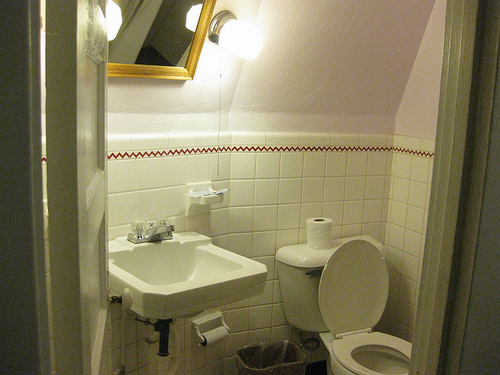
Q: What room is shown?
A: Bathroom.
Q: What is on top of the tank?
A: Roll of toilet paper.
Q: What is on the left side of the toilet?
A: Trash can.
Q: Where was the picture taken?
A: In a bathroom.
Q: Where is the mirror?
A: Above the sink.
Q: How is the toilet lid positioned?
A: Up.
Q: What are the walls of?
A: Tiles.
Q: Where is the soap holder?
A: To the right of the sink.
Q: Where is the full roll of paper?
A: On the toilet's tank.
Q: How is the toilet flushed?
A: With a handle on the left side of the tank.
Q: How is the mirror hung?
A: Tilted.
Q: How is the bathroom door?
A: Open.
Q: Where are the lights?
A: On both sides of the mirror.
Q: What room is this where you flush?
A: Bathroom.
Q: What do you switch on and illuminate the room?
A: Light.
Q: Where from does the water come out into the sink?
A: Faucet.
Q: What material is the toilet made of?
A: Porcelain.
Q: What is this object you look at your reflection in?
A: Mirror.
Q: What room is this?
A: Bathroom.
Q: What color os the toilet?
A: White.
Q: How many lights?
A: Two.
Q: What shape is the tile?
A: Square.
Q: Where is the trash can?
A: Next to toilet on floor.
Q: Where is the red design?
A: Tile.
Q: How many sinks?
A: One.